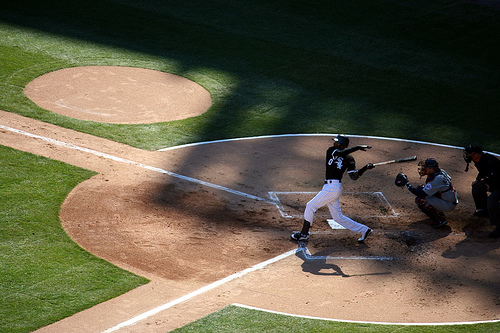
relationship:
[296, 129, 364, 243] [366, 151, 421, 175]
batter holding bat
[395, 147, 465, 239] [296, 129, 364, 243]
catcher behind batter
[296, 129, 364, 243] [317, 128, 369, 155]
batter wears helmet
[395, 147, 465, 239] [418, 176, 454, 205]
catcher wears uniform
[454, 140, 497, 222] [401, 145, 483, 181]
umpire wears mask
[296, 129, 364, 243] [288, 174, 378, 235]
batter wears pants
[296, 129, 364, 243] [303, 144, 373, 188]
batter wears jersey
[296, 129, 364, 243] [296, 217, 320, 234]
batter wears socks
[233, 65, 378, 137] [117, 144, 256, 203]
field has line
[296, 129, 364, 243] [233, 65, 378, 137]
batter in field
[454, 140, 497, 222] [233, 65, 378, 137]
umpire in field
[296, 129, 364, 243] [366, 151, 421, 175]
batter holds bat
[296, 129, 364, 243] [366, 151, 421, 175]
batter hold bat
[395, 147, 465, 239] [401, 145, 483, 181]
catcher wears mask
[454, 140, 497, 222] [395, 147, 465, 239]
umpire behind catcher